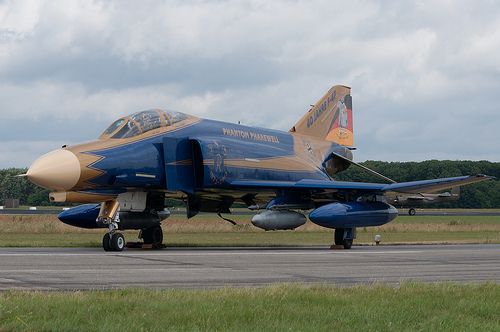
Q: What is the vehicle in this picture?
A: A Jet.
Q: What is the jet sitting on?
A: A runway.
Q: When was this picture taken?
A: Daytime.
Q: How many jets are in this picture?
A: 2.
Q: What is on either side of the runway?
A: Grass.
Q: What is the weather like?
A: Cloudy.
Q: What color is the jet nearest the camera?
A: Blue and gold.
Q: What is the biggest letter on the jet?
A: R.